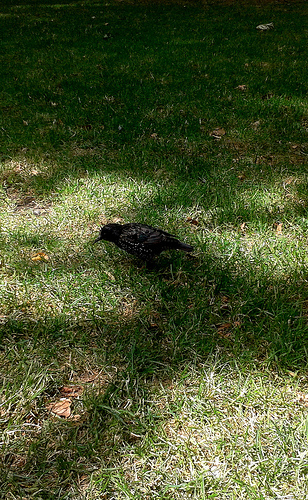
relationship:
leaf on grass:
[42, 378, 84, 429] [3, 2, 306, 487]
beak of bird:
[91, 236, 108, 246] [90, 216, 192, 286]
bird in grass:
[90, 216, 192, 286] [3, 2, 306, 487]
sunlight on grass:
[14, 155, 307, 343] [3, 2, 306, 487]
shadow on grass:
[1, 1, 296, 191] [3, 2, 306, 487]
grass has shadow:
[3, 2, 306, 487] [1, 1, 296, 191]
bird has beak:
[90, 216, 192, 286] [91, 236, 108, 246]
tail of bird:
[175, 236, 197, 268] [90, 216, 192, 286]